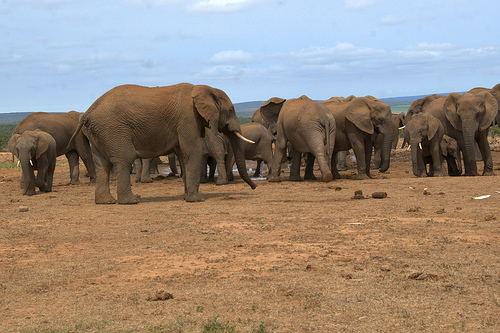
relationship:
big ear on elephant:
[184, 79, 226, 129] [64, 82, 256, 202]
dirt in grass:
[128, 250, 203, 277] [176, 210, 366, 312]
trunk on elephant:
[229, 118, 256, 189] [64, 82, 256, 202]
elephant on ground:
[7, 128, 58, 198] [3, 165, 483, 331]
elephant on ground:
[64, 82, 256, 202] [3, 165, 483, 331]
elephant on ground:
[10, 109, 94, 186] [3, 165, 483, 331]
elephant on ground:
[423, 81, 499, 176] [3, 165, 483, 331]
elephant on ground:
[260, 96, 336, 183] [3, 165, 483, 331]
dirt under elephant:
[0, 137, 498, 333] [66, 75, 258, 192]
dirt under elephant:
[0, 137, 498, 333] [266, 93, 329, 178]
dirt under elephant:
[0, 137, 498, 333] [317, 90, 397, 175]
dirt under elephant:
[0, 137, 498, 333] [399, 116, 444, 179]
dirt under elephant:
[0, 137, 498, 333] [445, 89, 494, 171]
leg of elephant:
[309, 154, 336, 184] [264, 86, 346, 176]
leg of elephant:
[409, 145, 426, 172] [264, 86, 346, 176]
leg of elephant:
[116, 155, 131, 194] [264, 86, 346, 176]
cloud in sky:
[0, 0, 499, 115] [3, 0, 493, 114]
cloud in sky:
[151, 0, 255, 19] [3, 0, 493, 114]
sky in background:
[3, 0, 493, 114] [4, 8, 483, 108]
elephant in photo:
[49, 72, 280, 209] [3, 9, 482, 313]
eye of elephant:
[220, 104, 235, 124] [258, 95, 336, 183]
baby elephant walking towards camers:
[9, 126, 62, 198] [69, 61, 466, 319]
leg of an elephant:
[90, 120, 139, 203] [64, 82, 256, 202]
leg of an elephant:
[92, 144, 117, 204] [64, 82, 256, 202]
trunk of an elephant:
[227, 125, 257, 189] [64, 82, 256, 202]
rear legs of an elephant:
[83, 145, 148, 207] [62, 77, 259, 208]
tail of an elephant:
[68, 120, 89, 157] [64, 82, 256, 202]